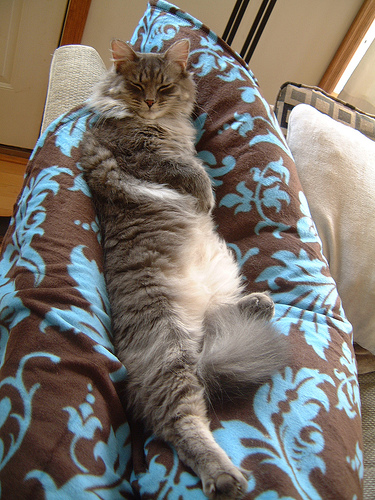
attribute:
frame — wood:
[317, 3, 371, 100]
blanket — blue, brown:
[3, 5, 368, 496]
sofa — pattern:
[276, 70, 374, 241]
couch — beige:
[23, 37, 116, 152]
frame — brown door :
[54, 1, 91, 58]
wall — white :
[80, 0, 373, 107]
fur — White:
[173, 220, 238, 327]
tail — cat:
[198, 300, 308, 408]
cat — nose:
[50, 21, 348, 483]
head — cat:
[92, 30, 202, 121]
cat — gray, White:
[76, 29, 305, 498]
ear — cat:
[162, 37, 191, 68]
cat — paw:
[65, 19, 340, 471]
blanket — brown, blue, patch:
[1, 310, 128, 498]